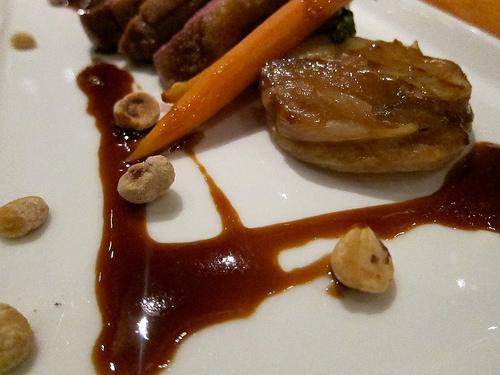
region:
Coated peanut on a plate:
[108, 153, 175, 204]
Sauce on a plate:
[80, 63, 446, 373]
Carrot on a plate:
[125, 0, 359, 164]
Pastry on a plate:
[263, 38, 471, 181]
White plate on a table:
[0, 0, 497, 372]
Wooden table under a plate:
[418, 0, 497, 38]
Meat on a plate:
[78, 0, 298, 87]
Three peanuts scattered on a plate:
[1, 30, 56, 372]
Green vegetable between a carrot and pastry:
[327, 8, 358, 45]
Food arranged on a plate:
[6, 0, 484, 207]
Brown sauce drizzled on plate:
[72, 60, 248, 360]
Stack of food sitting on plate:
[260, 43, 470, 178]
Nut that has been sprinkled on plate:
[115, 156, 180, 206]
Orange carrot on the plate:
[127, 0, 350, 155]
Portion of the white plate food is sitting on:
[281, 304, 496, 359]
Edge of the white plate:
[396, 1, 498, 54]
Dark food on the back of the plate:
[91, 3, 266, 74]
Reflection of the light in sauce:
[132, 315, 152, 340]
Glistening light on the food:
[260, 58, 337, 85]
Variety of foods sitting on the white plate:
[7, 3, 439, 372]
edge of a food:
[326, 103, 379, 168]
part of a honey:
[198, 260, 217, 282]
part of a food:
[355, 248, 390, 305]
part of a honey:
[193, 271, 226, 317]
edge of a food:
[360, 265, 378, 290]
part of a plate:
[297, 313, 324, 349]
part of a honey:
[178, 275, 236, 352]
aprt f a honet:
[191, 307, 228, 352]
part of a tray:
[300, 280, 320, 305]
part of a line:
[338, 234, 373, 316]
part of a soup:
[158, 269, 190, 315]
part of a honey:
[305, 255, 340, 316]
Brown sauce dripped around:
[73, 64, 498, 372]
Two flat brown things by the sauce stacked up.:
[261, 35, 473, 176]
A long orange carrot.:
[109, 0, 356, 164]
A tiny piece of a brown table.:
[431, 0, 498, 38]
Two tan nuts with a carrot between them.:
[111, 90, 175, 204]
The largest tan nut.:
[333, 223, 397, 293]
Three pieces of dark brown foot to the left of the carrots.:
[77, 1, 279, 83]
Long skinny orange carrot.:
[120, 0, 347, 164]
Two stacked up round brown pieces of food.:
[261, 41, 476, 174]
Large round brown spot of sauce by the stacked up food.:
[442, 140, 499, 232]